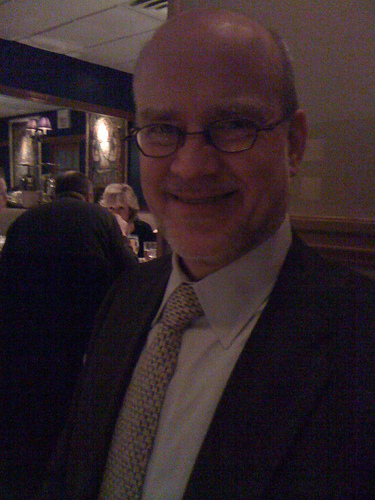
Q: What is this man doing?
A: Smiling.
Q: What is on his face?
A: Glasses.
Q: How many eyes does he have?
A: Two.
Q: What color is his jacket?
A: Black.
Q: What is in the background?
A: Two people.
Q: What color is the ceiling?
A: White.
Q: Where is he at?
A: A restaurant.